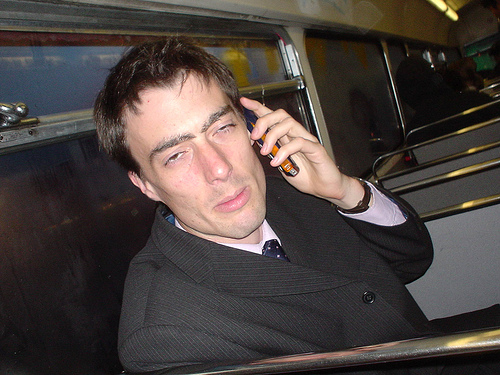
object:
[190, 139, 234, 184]
nose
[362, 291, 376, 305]
button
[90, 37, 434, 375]
man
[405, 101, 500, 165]
seats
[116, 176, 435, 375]
pinstripe suit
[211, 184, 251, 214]
mouth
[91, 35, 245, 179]
hair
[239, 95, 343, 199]
hand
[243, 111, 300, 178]
cell phone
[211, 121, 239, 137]
eye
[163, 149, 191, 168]
eye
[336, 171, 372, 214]
wristwatch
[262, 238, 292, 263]
tie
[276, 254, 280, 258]
dot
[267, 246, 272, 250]
dot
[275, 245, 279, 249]
dot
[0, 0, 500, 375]
bus